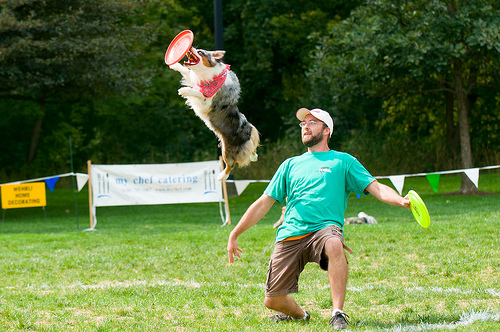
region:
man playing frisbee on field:
[268, 85, 398, 274]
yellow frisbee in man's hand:
[398, 195, 433, 240]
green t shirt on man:
[260, 136, 336, 242]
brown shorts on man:
[251, 219, 341, 306]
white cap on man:
[296, 91, 368, 138]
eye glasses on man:
[287, 112, 338, 128]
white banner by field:
[92, 147, 218, 215]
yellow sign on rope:
[1, 182, 51, 226]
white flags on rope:
[64, 166, 82, 194]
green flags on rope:
[424, 160, 441, 190]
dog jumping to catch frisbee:
[162, 24, 270, 181]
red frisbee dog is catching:
[161, 28, 191, 62]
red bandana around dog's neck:
[200, 58, 231, 100]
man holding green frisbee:
[230, 89, 435, 330]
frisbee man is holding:
[403, 185, 430, 230]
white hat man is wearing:
[297, 105, 340, 129]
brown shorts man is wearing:
[266, 223, 350, 294]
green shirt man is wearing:
[262, 152, 370, 226]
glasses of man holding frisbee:
[298, 115, 320, 126]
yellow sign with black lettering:
[1, 184, 43, 214]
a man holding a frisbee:
[265, 108, 450, 258]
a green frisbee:
[395, 193, 437, 223]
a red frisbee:
[155, 21, 197, 81]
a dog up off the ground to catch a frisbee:
[130, 20, 269, 225]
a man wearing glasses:
[285, 99, 354, 156]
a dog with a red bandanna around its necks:
[166, 41, 248, 115]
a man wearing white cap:
[288, 101, 341, 158]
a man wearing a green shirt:
[253, 138, 359, 268]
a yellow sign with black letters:
[1, 175, 52, 222]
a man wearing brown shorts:
[260, 202, 355, 308]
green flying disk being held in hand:
[405, 186, 437, 231]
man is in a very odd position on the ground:
[226, 107, 408, 329]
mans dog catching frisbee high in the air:
[163, 30, 258, 184]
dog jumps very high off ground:
[171, 49, 259, 183]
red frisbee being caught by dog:
[163, 24, 197, 64]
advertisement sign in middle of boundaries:
[83, 158, 235, 226]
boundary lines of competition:
[1, 158, 497, 228]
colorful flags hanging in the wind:
[225, 163, 498, 194]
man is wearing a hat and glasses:
[296, 108, 333, 138]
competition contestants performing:
[163, 28, 431, 330]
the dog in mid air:
[168, 45, 259, 181]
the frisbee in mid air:
[163, 29, 193, 66]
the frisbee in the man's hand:
[406, 189, 429, 228]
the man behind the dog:
[226, 107, 410, 329]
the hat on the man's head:
[295, 107, 333, 139]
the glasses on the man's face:
[298, 119, 327, 127]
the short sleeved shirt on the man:
[262, 149, 376, 244]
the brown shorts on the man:
[264, 224, 353, 297]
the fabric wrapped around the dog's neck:
[196, 63, 229, 98]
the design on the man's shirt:
[315, 164, 332, 174]